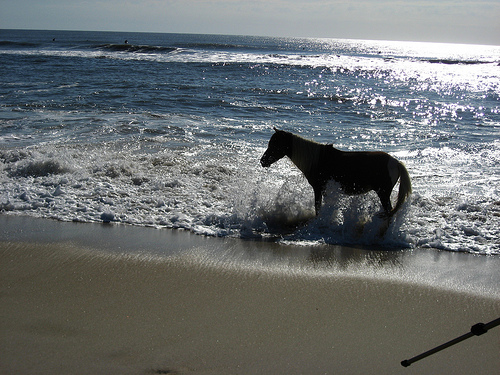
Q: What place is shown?
A: It is an ocean.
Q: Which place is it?
A: It is an ocean.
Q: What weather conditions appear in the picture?
A: It is clear.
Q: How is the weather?
A: It is clear.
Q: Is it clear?
A: Yes, it is clear.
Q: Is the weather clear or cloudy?
A: It is clear.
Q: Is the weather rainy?
A: No, it is clear.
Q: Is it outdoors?
A: Yes, it is outdoors.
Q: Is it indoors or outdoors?
A: It is outdoors.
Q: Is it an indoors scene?
A: No, it is outdoors.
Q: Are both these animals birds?
A: No, they are horses and birds.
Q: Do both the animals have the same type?
A: No, they are horses and birds.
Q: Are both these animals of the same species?
A: No, they are horses and birds.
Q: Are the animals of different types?
A: Yes, they are horses and birds.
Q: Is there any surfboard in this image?
A: No, there are no surfboards.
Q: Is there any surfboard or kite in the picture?
A: No, there are no surfboards or kites.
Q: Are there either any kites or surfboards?
A: No, there are no surfboards or kites.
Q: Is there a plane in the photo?
A: No, there are no airplanes.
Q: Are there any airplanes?
A: No, there are no airplanes.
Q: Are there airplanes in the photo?
A: No, there are no airplanes.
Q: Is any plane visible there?
A: No, there are no airplanes.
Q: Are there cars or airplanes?
A: No, there are no airplanes or cars.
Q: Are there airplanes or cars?
A: No, there are no airplanes or cars.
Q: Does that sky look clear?
A: Yes, the sky is clear.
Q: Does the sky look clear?
A: Yes, the sky is clear.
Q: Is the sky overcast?
A: No, the sky is clear.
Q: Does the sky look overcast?
A: No, the sky is clear.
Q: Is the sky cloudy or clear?
A: The sky is clear.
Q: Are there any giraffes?
A: No, there are no giraffes.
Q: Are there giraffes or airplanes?
A: No, there are no giraffes or airplanes.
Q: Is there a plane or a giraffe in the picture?
A: No, there are no giraffes or airplanes.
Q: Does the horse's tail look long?
A: Yes, the tail is long.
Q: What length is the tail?
A: The tail is long.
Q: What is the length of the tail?
A: The tail is long.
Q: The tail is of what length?
A: The tail is long.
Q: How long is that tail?
A: The tail is long.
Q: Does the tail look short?
A: No, the tail is long.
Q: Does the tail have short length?
A: No, the tail is long.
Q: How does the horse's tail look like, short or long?
A: The tail is long.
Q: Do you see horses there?
A: Yes, there is a horse.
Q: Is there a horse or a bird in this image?
A: Yes, there is a horse.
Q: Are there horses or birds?
A: Yes, there is a horse.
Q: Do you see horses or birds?
A: Yes, there is a horse.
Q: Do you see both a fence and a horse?
A: No, there is a horse but no fences.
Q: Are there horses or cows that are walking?
A: Yes, the horse is walking.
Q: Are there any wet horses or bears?
A: Yes, there is a wet horse.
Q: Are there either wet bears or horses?
A: Yes, there is a wet horse.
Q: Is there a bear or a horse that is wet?
A: Yes, the horse is wet.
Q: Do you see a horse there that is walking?
A: Yes, there is a horse that is walking.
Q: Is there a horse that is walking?
A: Yes, there is a horse that is walking.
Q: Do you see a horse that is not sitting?
A: Yes, there is a horse that is walking .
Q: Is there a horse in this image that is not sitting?
A: Yes, there is a horse that is walking.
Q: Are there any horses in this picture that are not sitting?
A: Yes, there is a horse that is walking.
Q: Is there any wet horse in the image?
A: Yes, there is a wet horse.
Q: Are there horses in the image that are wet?
A: Yes, there is a wet horse.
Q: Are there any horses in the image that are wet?
A: Yes, there is a horse that is wet.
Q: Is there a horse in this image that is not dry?
A: Yes, there is a wet horse.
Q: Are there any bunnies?
A: No, there are no bunnies.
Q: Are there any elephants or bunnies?
A: No, there are no bunnies or elephants.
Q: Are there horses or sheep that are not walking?
A: No, there is a horse but it is walking.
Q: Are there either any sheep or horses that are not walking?
A: No, there is a horse but it is walking.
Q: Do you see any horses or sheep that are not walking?
A: No, there is a horse but it is walking.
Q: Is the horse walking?
A: Yes, the horse is walking.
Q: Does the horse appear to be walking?
A: Yes, the horse is walking.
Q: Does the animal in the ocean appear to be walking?
A: Yes, the horse is walking.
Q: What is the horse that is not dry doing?
A: The horse is walking.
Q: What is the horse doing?
A: The horse is walking.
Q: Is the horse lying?
A: No, the horse is walking.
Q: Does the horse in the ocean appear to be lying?
A: No, the horse is walking.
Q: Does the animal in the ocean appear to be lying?
A: No, the horse is walking.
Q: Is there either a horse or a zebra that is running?
A: No, there is a horse but it is walking.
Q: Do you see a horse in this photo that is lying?
A: No, there is a horse but it is walking.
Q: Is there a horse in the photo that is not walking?
A: No, there is a horse but it is walking.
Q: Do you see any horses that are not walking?
A: No, there is a horse but it is walking.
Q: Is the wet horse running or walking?
A: The horse is walking.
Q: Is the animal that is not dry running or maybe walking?
A: The horse is walking.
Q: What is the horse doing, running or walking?
A: The horse is walking.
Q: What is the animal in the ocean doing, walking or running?
A: The horse is walking.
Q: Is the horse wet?
A: Yes, the horse is wet.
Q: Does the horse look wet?
A: Yes, the horse is wet.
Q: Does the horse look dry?
A: No, the horse is wet.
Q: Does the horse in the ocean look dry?
A: No, the horse is wet.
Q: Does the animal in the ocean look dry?
A: No, the horse is wet.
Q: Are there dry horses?
A: No, there is a horse but it is wet.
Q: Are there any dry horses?
A: No, there is a horse but it is wet.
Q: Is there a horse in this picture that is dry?
A: No, there is a horse but it is wet.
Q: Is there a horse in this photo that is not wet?
A: No, there is a horse but it is wet.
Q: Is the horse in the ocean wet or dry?
A: The horse is wet.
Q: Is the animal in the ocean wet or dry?
A: The horse is wet.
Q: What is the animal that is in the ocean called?
A: The animal is a horse.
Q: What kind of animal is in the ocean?
A: The animal is a horse.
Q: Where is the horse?
A: The horse is in the ocean.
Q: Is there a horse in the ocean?
A: Yes, there is a horse in the ocean.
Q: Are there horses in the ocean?
A: Yes, there is a horse in the ocean.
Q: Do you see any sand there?
A: Yes, there is sand.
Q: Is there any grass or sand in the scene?
A: Yes, there is sand.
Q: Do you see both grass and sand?
A: No, there is sand but no grass.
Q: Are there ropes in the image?
A: No, there are no ropes.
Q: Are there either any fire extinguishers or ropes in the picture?
A: No, there are no ropes or fire extinguishers.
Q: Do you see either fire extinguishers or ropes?
A: No, there are no ropes or fire extinguishers.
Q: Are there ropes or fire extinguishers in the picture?
A: No, there are no ropes or fire extinguishers.